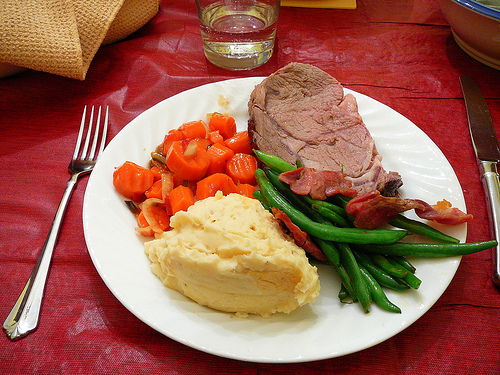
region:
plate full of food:
[114, 106, 421, 337]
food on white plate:
[101, 99, 413, 303]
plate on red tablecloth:
[104, 73, 494, 368]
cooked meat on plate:
[240, 58, 417, 207]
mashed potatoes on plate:
[146, 202, 343, 327]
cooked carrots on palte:
[123, 119, 277, 208]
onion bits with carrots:
[124, 123, 231, 227]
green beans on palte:
[249, 130, 436, 321]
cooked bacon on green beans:
[266, 159, 483, 279]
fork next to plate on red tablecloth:
[15, 93, 185, 367]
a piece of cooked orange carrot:
[113, 160, 153, 197]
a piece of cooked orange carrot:
[138, 203, 168, 236]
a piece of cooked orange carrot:
[165, 185, 192, 212]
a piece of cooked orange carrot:
[197, 173, 233, 200]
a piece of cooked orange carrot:
[226, 151, 255, 181]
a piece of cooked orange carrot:
[166, 139, 208, 175]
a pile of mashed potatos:
[144, 189, 320, 319]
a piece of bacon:
[350, 183, 470, 232]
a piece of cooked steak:
[250, 60, 398, 195]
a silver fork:
[6, 102, 109, 340]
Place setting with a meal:
[8, 0, 495, 366]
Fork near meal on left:
[22, 102, 106, 346]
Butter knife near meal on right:
[455, 70, 499, 190]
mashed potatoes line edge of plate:
[154, 195, 282, 308]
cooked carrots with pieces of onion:
[134, 125, 255, 195]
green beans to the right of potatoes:
[318, 226, 431, 298]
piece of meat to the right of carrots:
[245, 67, 341, 170]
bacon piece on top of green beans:
[348, 195, 471, 225]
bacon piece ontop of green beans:
[283, 165, 354, 201]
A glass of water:
[196, 23, 283, 65]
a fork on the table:
[27, 100, 82, 352]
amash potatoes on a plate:
[147, 225, 299, 310]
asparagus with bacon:
[263, 145, 445, 285]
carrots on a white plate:
[127, 132, 250, 204]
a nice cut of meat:
[261, 51, 387, 234]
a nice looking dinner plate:
[107, 81, 467, 308]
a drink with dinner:
[171, 12, 294, 74]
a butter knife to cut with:
[439, 53, 496, 157]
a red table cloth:
[17, 58, 126, 335]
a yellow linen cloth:
[16, 10, 100, 92]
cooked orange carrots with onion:
[160, 124, 240, 191]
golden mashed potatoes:
[174, 211, 285, 301]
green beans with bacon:
[265, 165, 413, 252]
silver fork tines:
[73, 102, 106, 152]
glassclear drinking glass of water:
[194, 2, 281, 74]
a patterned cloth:
[6, 7, 82, 65]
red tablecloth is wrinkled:
[352, 19, 459, 109]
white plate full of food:
[69, 60, 461, 370]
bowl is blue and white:
[465, 2, 499, 36]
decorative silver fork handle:
[0, 302, 41, 342]